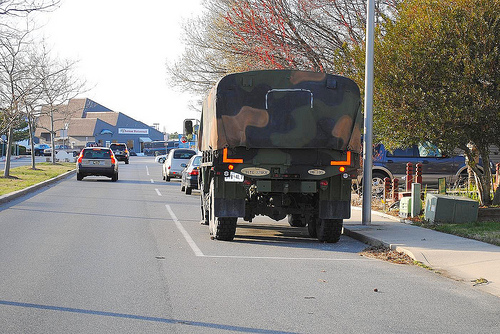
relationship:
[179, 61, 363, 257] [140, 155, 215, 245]
truck on road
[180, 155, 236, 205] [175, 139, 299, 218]
car in front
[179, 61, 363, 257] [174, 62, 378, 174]
truck has camoflauged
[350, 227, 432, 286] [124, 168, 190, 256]
leaves on street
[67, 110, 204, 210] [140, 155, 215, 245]
cars on road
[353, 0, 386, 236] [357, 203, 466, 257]
pole on sidewalk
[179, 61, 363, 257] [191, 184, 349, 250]
truck has tires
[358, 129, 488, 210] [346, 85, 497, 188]
suv on driveway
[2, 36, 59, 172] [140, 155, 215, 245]
trees on road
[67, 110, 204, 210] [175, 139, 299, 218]
cars in front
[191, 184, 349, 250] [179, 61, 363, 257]
tires of truck